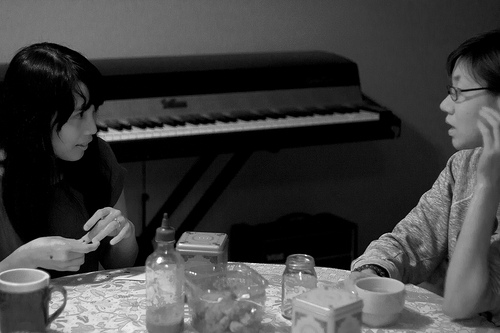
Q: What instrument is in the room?
A: Piano.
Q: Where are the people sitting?
A: Around table.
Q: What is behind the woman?
A: Keyboard.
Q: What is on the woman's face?
A: Glasses.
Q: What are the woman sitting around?
A: Table.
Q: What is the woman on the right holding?
A: Cup.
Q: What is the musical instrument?
A: Keyboard.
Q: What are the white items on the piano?
A: Keys.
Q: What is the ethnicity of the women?
A: Asian.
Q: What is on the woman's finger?
A: Ring.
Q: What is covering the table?
A: Tablecloth.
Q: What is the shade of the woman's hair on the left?
A: Black.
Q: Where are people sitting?
A: At table.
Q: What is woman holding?
A: Coffee cup.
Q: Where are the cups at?
A: Round table.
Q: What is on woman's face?
A: Glasses.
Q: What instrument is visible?
A: Piano.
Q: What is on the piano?
A: Keys.